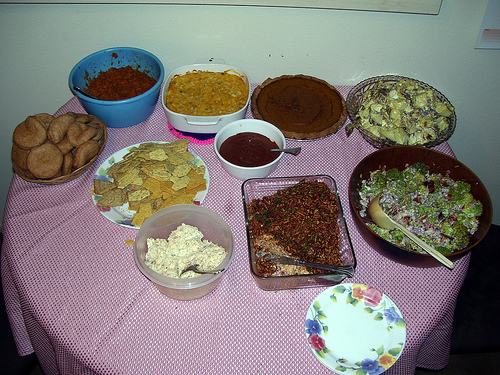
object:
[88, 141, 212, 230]
dish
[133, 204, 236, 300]
dish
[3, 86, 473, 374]
table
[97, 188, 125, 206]
crackers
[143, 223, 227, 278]
chicken salad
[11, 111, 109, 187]
basket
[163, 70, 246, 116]
corn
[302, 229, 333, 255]
food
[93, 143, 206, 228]
food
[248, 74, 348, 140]
pie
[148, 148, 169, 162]
chips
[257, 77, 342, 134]
food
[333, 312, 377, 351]
plate center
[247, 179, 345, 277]
food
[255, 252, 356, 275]
spoon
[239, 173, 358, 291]
dish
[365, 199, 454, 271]
server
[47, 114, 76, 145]
bread pieces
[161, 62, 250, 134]
dish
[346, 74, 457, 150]
bowl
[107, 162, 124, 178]
crackers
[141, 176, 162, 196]
cheese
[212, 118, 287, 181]
bowl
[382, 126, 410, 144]
food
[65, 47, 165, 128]
bowl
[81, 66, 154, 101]
salsa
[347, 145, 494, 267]
bowl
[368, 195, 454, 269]
spoon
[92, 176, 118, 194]
crackers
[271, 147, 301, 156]
spoon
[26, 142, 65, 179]
bread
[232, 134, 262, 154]
salsa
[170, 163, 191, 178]
chips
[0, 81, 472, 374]
cloth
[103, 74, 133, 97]
salsa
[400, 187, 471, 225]
food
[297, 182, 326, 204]
food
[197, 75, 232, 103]
food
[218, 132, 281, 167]
food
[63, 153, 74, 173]
food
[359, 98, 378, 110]
food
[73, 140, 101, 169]
food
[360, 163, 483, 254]
food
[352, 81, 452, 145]
food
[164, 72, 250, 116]
food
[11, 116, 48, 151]
bread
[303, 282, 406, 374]
plate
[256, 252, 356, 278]
knife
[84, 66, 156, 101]
chili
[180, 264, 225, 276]
spoon